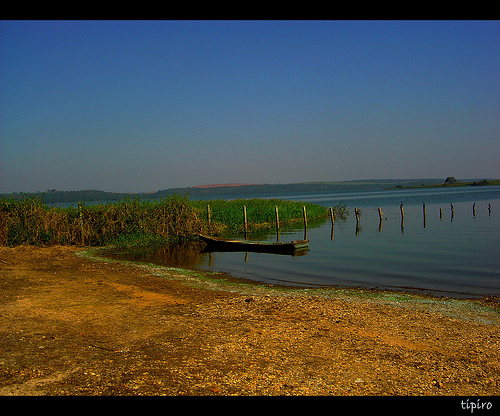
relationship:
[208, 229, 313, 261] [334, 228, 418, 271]
boat in water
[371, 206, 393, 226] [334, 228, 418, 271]
stump in water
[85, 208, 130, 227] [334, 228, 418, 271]
shrubs near water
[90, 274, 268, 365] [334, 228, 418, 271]
shore of water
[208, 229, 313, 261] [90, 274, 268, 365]
boat near shore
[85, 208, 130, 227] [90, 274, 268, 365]
shrubs near shore